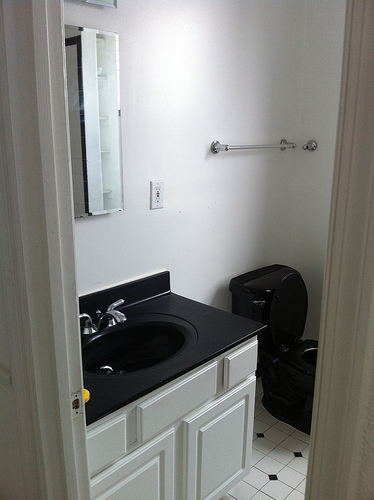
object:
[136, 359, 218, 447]
drawers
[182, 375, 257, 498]
cabinets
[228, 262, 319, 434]
black toilet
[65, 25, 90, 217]
mirror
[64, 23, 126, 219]
cabinet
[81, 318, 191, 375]
bathroom sink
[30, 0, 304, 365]
wall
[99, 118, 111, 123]
shelves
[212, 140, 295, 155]
rack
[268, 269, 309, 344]
lid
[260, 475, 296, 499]
tile